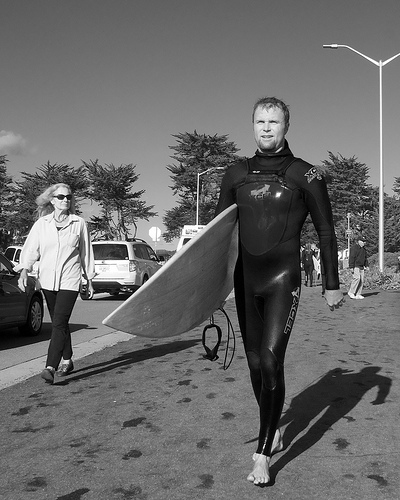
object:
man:
[212, 96, 346, 487]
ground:
[0, 289, 400, 500]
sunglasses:
[53, 194, 73, 200]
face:
[55, 186, 71, 210]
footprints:
[8, 305, 389, 500]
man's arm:
[214, 172, 234, 217]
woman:
[12, 183, 99, 384]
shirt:
[13, 209, 99, 292]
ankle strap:
[202, 308, 236, 370]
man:
[348, 237, 368, 300]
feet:
[246, 453, 270, 486]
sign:
[149, 227, 162, 241]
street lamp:
[196, 167, 225, 226]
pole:
[379, 58, 384, 272]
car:
[0, 252, 44, 337]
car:
[2, 245, 40, 279]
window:
[92, 244, 128, 260]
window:
[133, 244, 150, 259]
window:
[5, 248, 16, 261]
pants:
[42, 288, 79, 371]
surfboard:
[101, 203, 240, 339]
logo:
[284, 287, 300, 334]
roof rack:
[91, 238, 146, 242]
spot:
[196, 473, 213, 491]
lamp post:
[322, 43, 400, 272]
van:
[176, 224, 207, 252]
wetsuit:
[213, 137, 339, 459]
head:
[252, 97, 291, 150]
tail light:
[129, 260, 137, 271]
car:
[80, 238, 165, 301]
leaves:
[167, 128, 249, 179]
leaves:
[82, 158, 144, 203]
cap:
[357, 236, 366, 242]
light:
[319, 40, 399, 274]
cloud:
[0, 130, 37, 158]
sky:
[1, 0, 400, 156]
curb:
[0, 326, 136, 389]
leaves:
[319, 148, 369, 188]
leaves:
[364, 218, 377, 236]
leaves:
[21, 163, 89, 201]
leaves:
[14, 206, 31, 223]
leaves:
[119, 201, 158, 221]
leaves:
[164, 207, 178, 230]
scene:
[0, 0, 400, 499]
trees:
[0, 128, 400, 253]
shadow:
[260, 365, 392, 489]